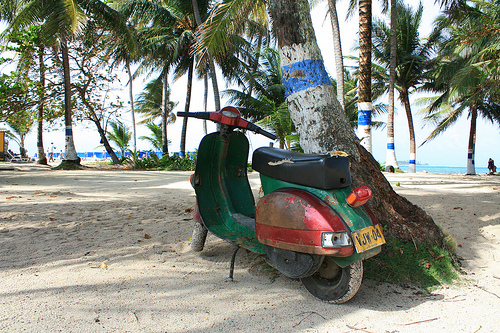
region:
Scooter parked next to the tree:
[172, 104, 386, 304]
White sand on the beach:
[1, 156, 498, 332]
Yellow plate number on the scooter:
[348, 223, 389, 253]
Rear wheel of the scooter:
[300, 254, 365, 306]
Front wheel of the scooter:
[188, 220, 208, 255]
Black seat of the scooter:
[251, 145, 353, 191]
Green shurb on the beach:
[106, 153, 197, 170]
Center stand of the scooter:
[223, 244, 243, 284]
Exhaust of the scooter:
[254, 221, 353, 256]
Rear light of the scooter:
[343, 184, 375, 207]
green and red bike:
[122, 87, 433, 315]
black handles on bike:
[187, 111, 272, 146]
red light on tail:
[335, 170, 379, 205]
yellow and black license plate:
[337, 213, 379, 268]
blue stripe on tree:
[276, 49, 354, 118]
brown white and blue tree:
[272, 13, 406, 227]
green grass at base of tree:
[360, 182, 456, 291]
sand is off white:
[75, 250, 207, 327]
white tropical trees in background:
[1, 13, 263, 127]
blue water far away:
[429, 161, 461, 177]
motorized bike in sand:
[181, 93, 393, 303]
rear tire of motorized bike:
[298, 254, 390, 312]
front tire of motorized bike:
[187, 195, 224, 260]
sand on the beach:
[14, 177, 481, 331]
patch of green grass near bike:
[383, 232, 451, 277]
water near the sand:
[383, 138, 496, 178]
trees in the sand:
[376, 0, 496, 186]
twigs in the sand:
[292, 306, 459, 331]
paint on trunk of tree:
[271, 39, 361, 158]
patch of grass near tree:
[134, 137, 202, 169]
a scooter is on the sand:
[171, 101, 379, 298]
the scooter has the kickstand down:
[226, 242, 242, 282]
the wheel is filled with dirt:
[300, 246, 360, 297]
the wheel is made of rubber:
[300, 245, 365, 300]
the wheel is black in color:
[303, 248, 363, 303]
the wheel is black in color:
[190, 221, 206, 251]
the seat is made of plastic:
[258, 142, 351, 189]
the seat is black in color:
[252, 144, 354, 194]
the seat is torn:
[327, 147, 347, 157]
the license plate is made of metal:
[353, 223, 387, 253]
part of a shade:
[160, 300, 162, 302]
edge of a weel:
[280, 267, 295, 285]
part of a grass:
[389, 258, 428, 300]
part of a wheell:
[338, 256, 368, 291]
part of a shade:
[180, 271, 216, 299]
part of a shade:
[94, 213, 126, 246]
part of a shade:
[78, 236, 115, 270]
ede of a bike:
[188, 193, 209, 224]